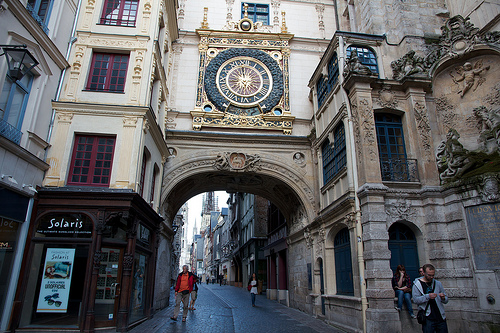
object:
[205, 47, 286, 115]
clock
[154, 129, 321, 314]
archway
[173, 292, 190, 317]
pants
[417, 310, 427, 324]
bag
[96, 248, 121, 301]
window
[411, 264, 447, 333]
man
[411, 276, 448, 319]
hoodie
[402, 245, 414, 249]
part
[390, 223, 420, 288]
door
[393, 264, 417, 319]
person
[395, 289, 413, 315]
blue jeans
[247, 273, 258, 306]
person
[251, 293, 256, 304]
jeans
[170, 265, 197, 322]
man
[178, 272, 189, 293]
shirt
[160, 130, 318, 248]
arch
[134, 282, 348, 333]
walkway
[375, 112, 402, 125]
window part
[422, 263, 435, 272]
hair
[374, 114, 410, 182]
window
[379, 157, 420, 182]
iron gate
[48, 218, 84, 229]
lettering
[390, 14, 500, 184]
design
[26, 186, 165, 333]
store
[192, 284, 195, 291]
shirt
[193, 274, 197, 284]
arm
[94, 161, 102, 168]
windows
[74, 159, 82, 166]
window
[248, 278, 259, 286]
shirt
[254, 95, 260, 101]
numerals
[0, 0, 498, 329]
building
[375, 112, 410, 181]
gate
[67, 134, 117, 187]
framing